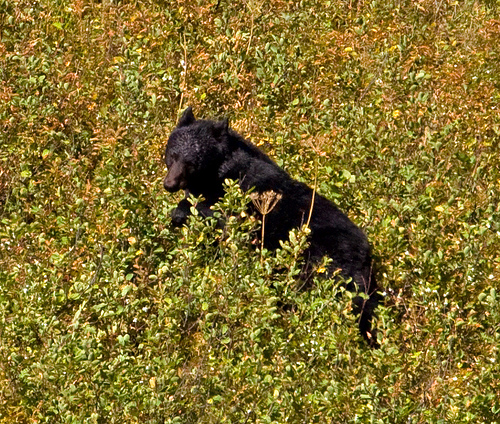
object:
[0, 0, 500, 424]
grass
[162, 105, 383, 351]
bear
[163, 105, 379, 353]
dark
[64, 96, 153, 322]
these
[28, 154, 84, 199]
tall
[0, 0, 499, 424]
plants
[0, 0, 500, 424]
green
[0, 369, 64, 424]
brown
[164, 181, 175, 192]
nose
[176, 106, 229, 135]
ears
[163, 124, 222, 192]
head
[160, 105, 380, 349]
black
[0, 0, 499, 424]
brush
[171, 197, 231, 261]
leg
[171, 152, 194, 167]
eyes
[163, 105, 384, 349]
fur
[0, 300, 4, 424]
plant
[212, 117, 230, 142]
left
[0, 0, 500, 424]
leaves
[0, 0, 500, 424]
field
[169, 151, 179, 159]
eye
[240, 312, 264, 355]
tall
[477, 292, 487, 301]
leaf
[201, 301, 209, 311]
leaf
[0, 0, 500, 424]
underbrush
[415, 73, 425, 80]
leaf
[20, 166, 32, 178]
leaf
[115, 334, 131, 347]
leaf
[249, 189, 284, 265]
twig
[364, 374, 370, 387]
leaf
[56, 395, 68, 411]
leaf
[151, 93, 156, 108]
leaf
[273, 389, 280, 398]
leaf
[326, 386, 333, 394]
leaf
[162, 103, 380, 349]
animal